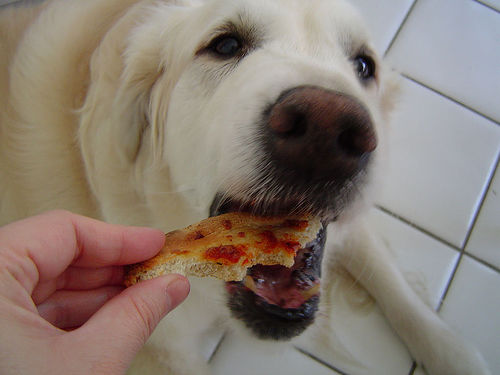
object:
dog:
[0, 0, 497, 373]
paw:
[416, 343, 490, 374]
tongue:
[228, 201, 267, 212]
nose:
[274, 87, 374, 169]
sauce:
[203, 244, 243, 264]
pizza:
[120, 207, 323, 290]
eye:
[352, 45, 382, 86]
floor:
[155, 1, 496, 373]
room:
[0, 0, 498, 375]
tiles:
[376, 0, 499, 125]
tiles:
[410, 251, 498, 374]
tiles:
[288, 203, 461, 373]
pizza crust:
[125, 205, 323, 288]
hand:
[0, 209, 190, 375]